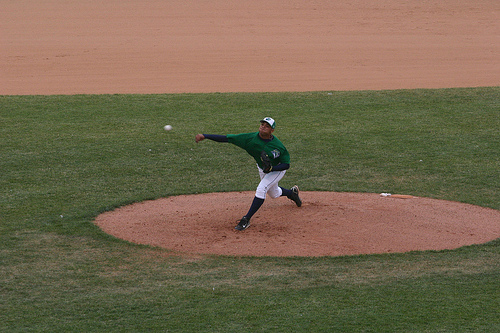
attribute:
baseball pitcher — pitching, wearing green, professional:
[198, 119, 305, 232]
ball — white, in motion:
[163, 122, 177, 135]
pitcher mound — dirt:
[99, 182, 498, 260]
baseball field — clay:
[1, 2, 495, 330]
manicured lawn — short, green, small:
[1, 85, 498, 332]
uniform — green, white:
[208, 128, 294, 223]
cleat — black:
[237, 215, 251, 231]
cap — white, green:
[260, 115, 278, 131]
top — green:
[226, 131, 291, 175]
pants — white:
[253, 162, 284, 201]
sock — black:
[243, 196, 264, 221]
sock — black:
[277, 184, 293, 202]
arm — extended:
[197, 132, 253, 147]